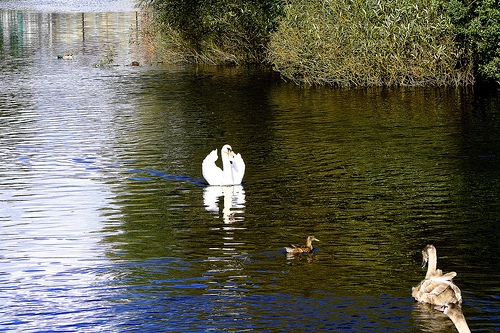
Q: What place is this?
A: It is a river.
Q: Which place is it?
A: It is a river.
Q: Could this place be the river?
A: Yes, it is the river.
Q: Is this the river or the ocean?
A: It is the river.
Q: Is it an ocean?
A: No, it is a river.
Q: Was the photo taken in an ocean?
A: No, the picture was taken in a river.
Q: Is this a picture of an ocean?
A: No, the picture is showing a river.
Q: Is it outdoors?
A: Yes, it is outdoors.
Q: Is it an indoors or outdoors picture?
A: It is outdoors.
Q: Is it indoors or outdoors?
A: It is outdoors.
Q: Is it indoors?
A: No, it is outdoors.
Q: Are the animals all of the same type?
A: No, there are both swans and birds.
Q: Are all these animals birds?
A: No, there are both swans and birds.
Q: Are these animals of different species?
A: Yes, they are swans and birds.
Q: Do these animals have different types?
A: Yes, they are swans and birds.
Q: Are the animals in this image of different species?
A: Yes, they are swans and birds.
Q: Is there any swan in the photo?
A: Yes, there is a swan.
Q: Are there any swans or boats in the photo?
A: Yes, there is a swan.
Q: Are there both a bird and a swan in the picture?
A: Yes, there are both a swan and a bird.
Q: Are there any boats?
A: No, there are no boats.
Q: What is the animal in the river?
A: The animal is a swan.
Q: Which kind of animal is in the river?
A: The animal is a swan.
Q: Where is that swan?
A: The swan is in the river.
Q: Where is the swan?
A: The swan is in the river.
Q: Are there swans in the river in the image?
A: Yes, there is a swan in the river.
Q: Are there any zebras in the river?
A: No, there is a swan in the river.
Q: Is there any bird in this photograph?
A: Yes, there are birds.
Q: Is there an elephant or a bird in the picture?
A: Yes, there are birds.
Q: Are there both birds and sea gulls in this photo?
A: No, there are birds but no seagulls.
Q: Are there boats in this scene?
A: No, there are no boats.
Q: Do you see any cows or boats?
A: No, there are no boats or cows.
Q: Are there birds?
A: Yes, there are birds.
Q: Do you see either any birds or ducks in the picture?
A: Yes, there are birds.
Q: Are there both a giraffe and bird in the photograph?
A: No, there are birds but no giraffes.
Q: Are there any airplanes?
A: No, there are no airplanes.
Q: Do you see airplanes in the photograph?
A: No, there are no airplanes.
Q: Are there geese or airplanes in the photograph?
A: No, there are no airplanes or geese.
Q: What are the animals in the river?
A: The animals are birds.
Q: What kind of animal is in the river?
A: The animals are birds.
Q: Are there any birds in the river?
A: Yes, there are birds in the river.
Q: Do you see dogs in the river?
A: No, there are birds in the river.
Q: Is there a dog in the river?
A: No, there are birds in the river.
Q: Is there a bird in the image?
A: Yes, there are birds.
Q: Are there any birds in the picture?
A: Yes, there are birds.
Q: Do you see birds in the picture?
A: Yes, there are birds.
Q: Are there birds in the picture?
A: Yes, there are birds.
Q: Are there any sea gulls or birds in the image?
A: Yes, there are birds.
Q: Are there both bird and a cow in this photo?
A: No, there are birds but no cows.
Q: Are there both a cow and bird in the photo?
A: No, there are birds but no cows.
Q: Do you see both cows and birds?
A: No, there are birds but no cows.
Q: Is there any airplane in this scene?
A: No, there are no airplanes.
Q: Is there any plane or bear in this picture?
A: No, there are no airplanes or bears.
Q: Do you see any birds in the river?
A: Yes, there are birds in the river.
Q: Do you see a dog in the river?
A: No, there are birds in the river.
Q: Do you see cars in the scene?
A: No, there are no cars.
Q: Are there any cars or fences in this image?
A: No, there are no cars or fences.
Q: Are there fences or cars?
A: No, there are no cars or fences.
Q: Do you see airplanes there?
A: No, there are no airplanes.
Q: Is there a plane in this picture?
A: No, there are no airplanes.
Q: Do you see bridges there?
A: No, there are no bridges.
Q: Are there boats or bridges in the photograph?
A: No, there are no bridges or boats.